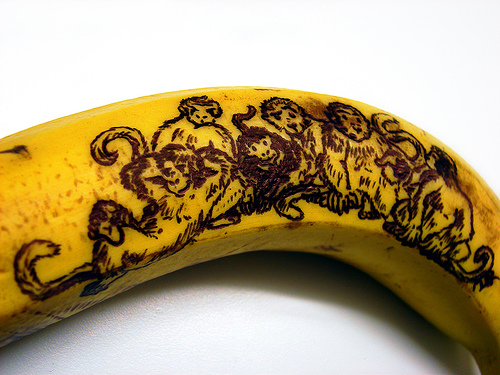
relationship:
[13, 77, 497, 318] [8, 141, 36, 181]
banana with brown spots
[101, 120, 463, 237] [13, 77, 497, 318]
6 monkeys on banana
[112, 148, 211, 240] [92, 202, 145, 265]
monkey with crossed legs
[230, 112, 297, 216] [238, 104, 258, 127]
monkey with s shaped tail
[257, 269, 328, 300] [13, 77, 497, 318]
shadow of banana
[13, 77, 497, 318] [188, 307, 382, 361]
banana on plate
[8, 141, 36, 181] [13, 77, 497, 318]
brown spots on banana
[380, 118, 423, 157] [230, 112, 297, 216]
tail over monkey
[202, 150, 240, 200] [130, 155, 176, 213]
black lines on arm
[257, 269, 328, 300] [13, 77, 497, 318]
shadow on banana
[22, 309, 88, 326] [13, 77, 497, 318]
scratch on banana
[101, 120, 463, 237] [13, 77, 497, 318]
6 monkeys drawn on banana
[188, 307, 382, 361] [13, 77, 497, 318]
plate under banana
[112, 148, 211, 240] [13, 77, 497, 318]
monkey on banana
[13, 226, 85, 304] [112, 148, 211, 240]
tail of monkey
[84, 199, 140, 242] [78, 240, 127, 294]
leg resting on leg